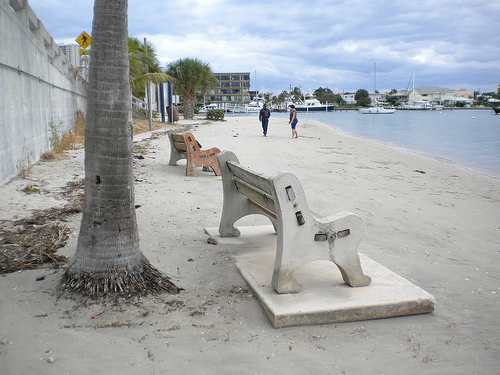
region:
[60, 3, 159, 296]
coconut tree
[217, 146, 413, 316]
it is a bench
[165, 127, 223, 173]
it is brown color bench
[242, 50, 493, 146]
it is a beach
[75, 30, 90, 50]
road crossing signal board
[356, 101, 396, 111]
it is a boat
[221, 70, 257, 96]
it is a building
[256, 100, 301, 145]
people walking on the sand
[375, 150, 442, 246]
it is beach sand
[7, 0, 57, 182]
it is compound wall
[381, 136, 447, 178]
water at the edge of sand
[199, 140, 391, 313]
a wood and concrete bench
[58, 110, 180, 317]
a palm tree in the sand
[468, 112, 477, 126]
a white buoy in the water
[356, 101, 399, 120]
a white boat in the water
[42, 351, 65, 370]
a rock on the sand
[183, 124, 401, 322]
this is a bench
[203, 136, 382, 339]
the bench is white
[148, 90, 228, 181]
this is a brown bench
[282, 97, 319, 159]
this is a person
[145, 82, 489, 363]
benches facing the water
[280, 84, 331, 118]
this is a boat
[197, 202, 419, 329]
white base of bench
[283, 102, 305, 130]
woman wearing blue clothing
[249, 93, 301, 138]
people walking by the seaside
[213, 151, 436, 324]
bench with wooden slats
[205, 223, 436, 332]
a concrete slab supporting bench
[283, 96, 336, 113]
blue and white boat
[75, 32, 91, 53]
yellow and black street sign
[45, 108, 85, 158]
dry brown weeds growing along wall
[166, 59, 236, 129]
palm trees standing in the sand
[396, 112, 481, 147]
calm, blue sea water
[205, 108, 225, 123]
small green bush growing in sand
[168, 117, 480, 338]
benches in front the ocean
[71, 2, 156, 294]
a trunk of a tree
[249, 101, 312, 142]
two people in the beach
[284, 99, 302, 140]
woman wears blue suit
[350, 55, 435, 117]
boats in the water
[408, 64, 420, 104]
a pole in a boat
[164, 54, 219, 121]
the tree is green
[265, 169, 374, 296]
the side of bench is cement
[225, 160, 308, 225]
planks of bench is wood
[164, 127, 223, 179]
bench is made of wood